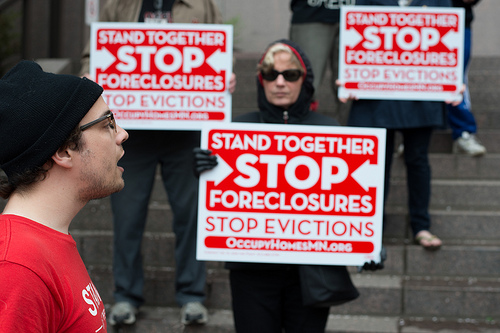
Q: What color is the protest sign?
A: Red and white.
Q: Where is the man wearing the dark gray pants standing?
A: On the steps.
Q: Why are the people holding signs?
A: They are protesting.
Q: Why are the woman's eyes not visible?
A: They are covered by sunglasses.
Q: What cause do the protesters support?
A: Stopping foreclosures.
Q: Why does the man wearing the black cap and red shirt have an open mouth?
A: He is speaking.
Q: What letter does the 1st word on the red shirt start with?
A: The letter "S".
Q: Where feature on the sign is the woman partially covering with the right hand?
A: Arrow.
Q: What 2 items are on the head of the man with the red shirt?
A: Cap and eyeglasses.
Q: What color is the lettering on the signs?
A: White.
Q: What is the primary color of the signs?
A: Red.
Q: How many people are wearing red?
A: Two.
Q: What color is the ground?
A: Grey.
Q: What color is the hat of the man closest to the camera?
A: Black.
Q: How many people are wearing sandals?
A: One.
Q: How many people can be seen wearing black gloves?
A: One.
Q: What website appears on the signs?
A: OccupyHomesMN.org.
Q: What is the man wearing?
A: A red shirt.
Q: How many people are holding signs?
A: Three.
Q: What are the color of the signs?
A: Red and white.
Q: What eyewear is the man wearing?
A: Eyeglasses.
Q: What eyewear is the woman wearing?
A: Sunglasses.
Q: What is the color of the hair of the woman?
A: Blonde.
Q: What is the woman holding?
A: A sign.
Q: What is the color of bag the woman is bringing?
A: Black.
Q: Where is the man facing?
A: At the right.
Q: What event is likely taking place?
A: Protest.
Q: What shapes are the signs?
A: Rectangles.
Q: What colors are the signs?
A: Red and white.